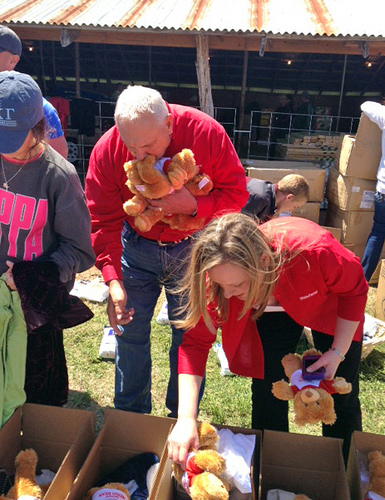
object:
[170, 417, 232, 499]
bear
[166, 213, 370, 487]
lady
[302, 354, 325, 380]
phone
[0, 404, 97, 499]
boxes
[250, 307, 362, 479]
pants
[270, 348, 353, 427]
teddy bear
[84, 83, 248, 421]
man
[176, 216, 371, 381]
shirt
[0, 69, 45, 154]
hat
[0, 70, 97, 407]
woman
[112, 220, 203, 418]
pants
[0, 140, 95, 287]
shirt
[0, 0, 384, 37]
roof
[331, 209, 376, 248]
box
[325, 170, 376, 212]
box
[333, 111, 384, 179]
box